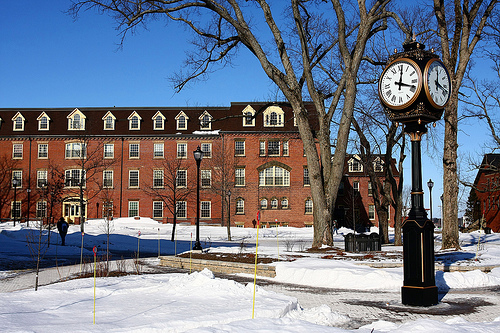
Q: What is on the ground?
A: Snow.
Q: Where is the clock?
A: On the post.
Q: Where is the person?
A: Walking on the path.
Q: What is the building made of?
A: Brick.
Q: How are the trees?
A: Leafless.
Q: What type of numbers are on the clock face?
A: Roman numerals.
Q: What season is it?
A: Winter.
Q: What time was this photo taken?
A: 12:20.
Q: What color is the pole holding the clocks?
A: Black.